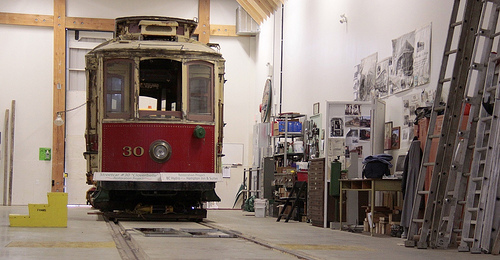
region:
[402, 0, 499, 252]
several ladders stacked against wall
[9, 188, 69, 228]
set of yellow stairs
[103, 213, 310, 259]
train tracks in cement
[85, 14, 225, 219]
train is on tracks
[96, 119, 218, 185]
red panel on train front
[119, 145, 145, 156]
gold number 30 on train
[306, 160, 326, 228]
metal tool cabinet drawers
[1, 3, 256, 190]
large wooden beams on wall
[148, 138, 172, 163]
single large headlight on train car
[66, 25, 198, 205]
large white door behind train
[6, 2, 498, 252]
a tolley is on tracks in a barn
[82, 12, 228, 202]
the trolley is red and white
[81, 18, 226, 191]
the trolley is rusted and a window is missing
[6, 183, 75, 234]
yellow steps are by the trolley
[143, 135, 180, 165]
a headlight is on the front of the trolley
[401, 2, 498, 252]
ladders are in the trolley barn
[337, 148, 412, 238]
a computer is on a workbench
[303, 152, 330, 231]
a cabinet with drawers is in the barn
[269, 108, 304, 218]
a shelf has items on it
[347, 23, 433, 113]
posters are on the wall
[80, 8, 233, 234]
red trolley car in garage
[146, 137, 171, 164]
headlight on trolley car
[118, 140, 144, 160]
number '30' on front of trolley car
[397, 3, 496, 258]
several tall ladders in garage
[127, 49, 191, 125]
open front window of trolley car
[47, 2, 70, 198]
wooden beam in wall of garage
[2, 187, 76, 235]
yellow stairs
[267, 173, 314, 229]
fold up chair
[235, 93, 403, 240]
storage containers for equipment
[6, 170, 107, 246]
a small staircase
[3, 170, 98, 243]
a wooden stepping stool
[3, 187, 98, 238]
a yellow staircase that is movable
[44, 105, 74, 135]
a white light bulb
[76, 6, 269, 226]
the cable car has chipped paint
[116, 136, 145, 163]
the number 30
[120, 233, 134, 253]
track on the floor.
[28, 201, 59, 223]
steps near the train.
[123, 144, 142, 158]
number on the train.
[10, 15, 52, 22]
wooden plank on the wall.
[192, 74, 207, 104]
window on the train.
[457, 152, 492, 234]
ladder in the warehouse.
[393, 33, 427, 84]
poster on the wall.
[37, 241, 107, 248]
yellow paint on the ground.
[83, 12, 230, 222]
trolley train on display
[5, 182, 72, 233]
small yellow stairs by train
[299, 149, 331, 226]
file drawer against wall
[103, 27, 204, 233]
red and brown vintage tram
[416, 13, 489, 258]
metal ladders against the wall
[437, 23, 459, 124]
metal ladder against the wall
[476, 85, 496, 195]
metal ladders against the wall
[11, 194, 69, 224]
small yellow steps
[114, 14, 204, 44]
roof of the old tram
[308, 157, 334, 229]
brown and gray tool cabinet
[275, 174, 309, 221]
small black chair on the floor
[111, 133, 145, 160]
numbering gold on the red tram